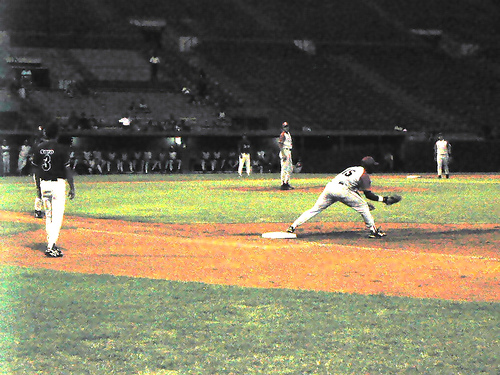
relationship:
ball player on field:
[285, 155, 400, 240] [3, 151, 470, 353]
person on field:
[26, 119, 91, 257] [3, 151, 470, 353]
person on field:
[257, 106, 302, 191] [3, 151, 470, 353]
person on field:
[415, 122, 467, 183] [3, 151, 470, 353]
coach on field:
[237, 131, 252, 178] [3, 151, 470, 353]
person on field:
[32, 121, 76, 257] [1, 170, 484, 354]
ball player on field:
[285, 155, 400, 240] [1, 173, 484, 373]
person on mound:
[277, 123, 297, 192] [215, 183, 429, 193]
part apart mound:
[227, 179, 319, 193] [223, 182, 398, 193]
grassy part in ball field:
[146, 277, 225, 321] [36, 276, 315, 369]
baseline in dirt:
[65, 219, 484, 264] [0, 210, 499, 306]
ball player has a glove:
[285, 152, 385, 240] [381, 186, 408, 215]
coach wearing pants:
[235, 130, 253, 174] [282, 181, 373, 232]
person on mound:
[277, 123, 297, 192] [278, 180, 295, 199]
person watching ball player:
[277, 123, 297, 192] [285, 155, 400, 240]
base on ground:
[259, 229, 296, 239] [2, 170, 497, 372]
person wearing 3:
[32, 121, 76, 257] [38, 155, 51, 172]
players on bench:
[74, 144, 236, 172] [71, 148, 263, 173]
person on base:
[437, 133, 452, 181] [259, 229, 296, 239]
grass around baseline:
[51, 296, 215, 368] [60, 264, 253, 294]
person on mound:
[277, 123, 297, 192] [218, 178, 333, 203]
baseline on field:
[65, 222, 484, 265] [4, 141, 491, 368]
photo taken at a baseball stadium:
[4, 7, 492, 319] [0, 4, 495, 370]